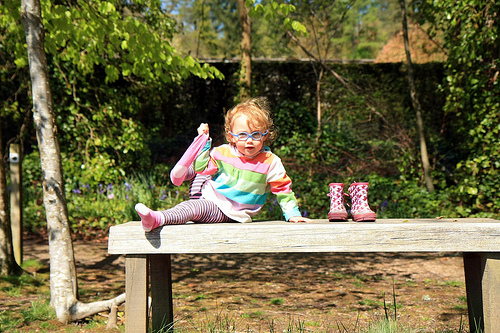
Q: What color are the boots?
A: Pink and white.